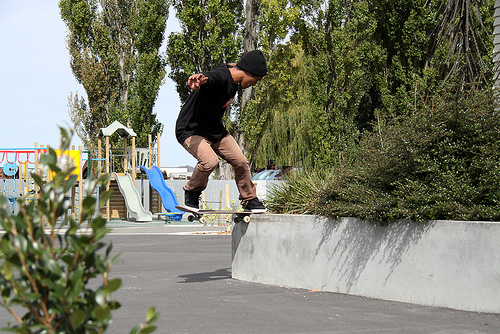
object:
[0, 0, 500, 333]
park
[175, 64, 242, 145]
shirt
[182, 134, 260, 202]
pants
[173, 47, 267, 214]
man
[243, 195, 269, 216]
shoe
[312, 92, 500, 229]
bush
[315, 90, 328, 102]
leaves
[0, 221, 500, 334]
sidewalk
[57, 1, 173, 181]
tree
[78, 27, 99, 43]
leaves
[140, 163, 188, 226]
slide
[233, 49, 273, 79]
cap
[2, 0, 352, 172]
sky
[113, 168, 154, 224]
slide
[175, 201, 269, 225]
skateboard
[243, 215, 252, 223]
wheels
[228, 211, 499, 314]
wall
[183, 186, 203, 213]
shoe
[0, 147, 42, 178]
monkey bars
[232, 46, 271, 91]
head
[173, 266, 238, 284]
shadow